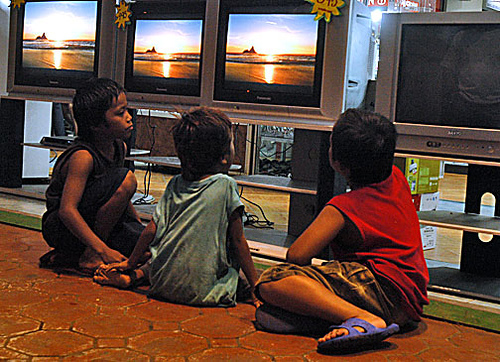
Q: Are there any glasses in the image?
A: No, there are no glasses.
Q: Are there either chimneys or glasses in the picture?
A: No, there are no glasses or chimneys.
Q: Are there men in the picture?
A: No, there are no men.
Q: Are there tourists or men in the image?
A: No, there are no men or tourists.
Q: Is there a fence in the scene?
A: No, there are no fences.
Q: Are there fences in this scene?
A: No, there are no fences.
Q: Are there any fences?
A: No, there are no fences.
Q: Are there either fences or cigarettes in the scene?
A: No, there are no fences or cigarettes.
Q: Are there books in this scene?
A: No, there are no books.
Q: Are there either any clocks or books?
A: No, there are no books or clocks.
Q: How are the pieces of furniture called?
A: The pieces of furniture are shelves.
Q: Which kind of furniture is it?
A: The pieces of furniture are shelves.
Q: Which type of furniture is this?
A: These are shelves.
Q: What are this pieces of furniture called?
A: These are shelves.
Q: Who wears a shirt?
A: The boy wears a shirt.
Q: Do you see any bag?
A: No, there are no bags.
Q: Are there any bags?
A: No, there are no bags.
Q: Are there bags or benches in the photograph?
A: No, there are no bags or benches.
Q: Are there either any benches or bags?
A: No, there are no bags or benches.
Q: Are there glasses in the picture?
A: No, there are no glasses.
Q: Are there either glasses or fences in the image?
A: No, there are no glasses or fences.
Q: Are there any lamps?
A: No, there are no lamps.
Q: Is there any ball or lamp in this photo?
A: No, there are no lamps or balls.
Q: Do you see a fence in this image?
A: No, there are no fences.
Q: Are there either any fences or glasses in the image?
A: No, there are no fences or glasses.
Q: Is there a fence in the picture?
A: No, there are no fences.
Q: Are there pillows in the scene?
A: No, there are no pillows.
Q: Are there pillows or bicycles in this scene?
A: No, there are no pillows or bicycles.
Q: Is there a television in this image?
A: Yes, there are televisions.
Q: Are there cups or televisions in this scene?
A: Yes, there are televisions.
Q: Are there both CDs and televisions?
A: No, there are televisions but no cds.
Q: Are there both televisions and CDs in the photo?
A: No, there are televisions but no cds.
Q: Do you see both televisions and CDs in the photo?
A: No, there are televisions but no cds.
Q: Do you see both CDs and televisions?
A: No, there are televisions but no cds.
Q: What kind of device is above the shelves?
A: The devices are televisions.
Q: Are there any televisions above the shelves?
A: Yes, there are televisions above the shelves.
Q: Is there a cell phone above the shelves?
A: No, there are televisions above the shelves.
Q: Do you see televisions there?
A: Yes, there is a television.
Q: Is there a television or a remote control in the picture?
A: Yes, there is a television.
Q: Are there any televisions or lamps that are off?
A: Yes, the television is off.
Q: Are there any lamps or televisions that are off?
A: Yes, the television is off.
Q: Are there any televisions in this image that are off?
A: Yes, there is a television that is off.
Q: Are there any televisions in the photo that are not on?
A: Yes, there is a television that is off.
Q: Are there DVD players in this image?
A: No, there are no DVD players.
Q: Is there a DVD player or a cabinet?
A: No, there are no DVD players or cabinets.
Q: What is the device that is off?
A: The device is a television.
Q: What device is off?
A: The device is a television.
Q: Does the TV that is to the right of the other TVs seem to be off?
A: Yes, the television is off.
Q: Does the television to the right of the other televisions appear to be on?
A: No, the television is off.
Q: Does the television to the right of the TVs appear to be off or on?
A: The TV is off.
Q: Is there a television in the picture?
A: Yes, there is a television.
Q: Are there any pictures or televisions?
A: Yes, there is a television.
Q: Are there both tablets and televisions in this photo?
A: No, there is a television but no tablets.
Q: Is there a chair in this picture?
A: No, there are no chairs.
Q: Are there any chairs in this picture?
A: No, there are no chairs.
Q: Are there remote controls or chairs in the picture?
A: No, there are no chairs or remote controls.